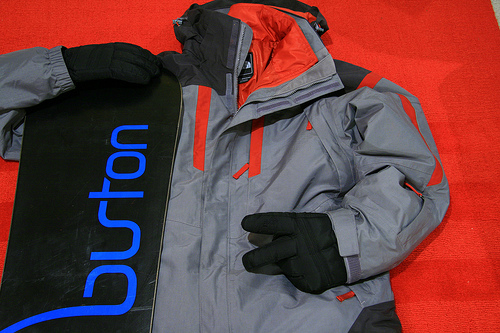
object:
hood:
[172, 0, 338, 70]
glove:
[63, 39, 162, 85]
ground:
[317, 127, 373, 182]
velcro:
[224, 19, 254, 108]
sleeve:
[322, 58, 451, 283]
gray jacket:
[1, 1, 450, 331]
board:
[0, 67, 184, 333]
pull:
[232, 163, 248, 180]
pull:
[336, 290, 355, 303]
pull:
[305, 121, 312, 130]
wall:
[308, 108, 362, 158]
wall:
[192, 39, 259, 111]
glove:
[236, 206, 346, 294]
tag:
[238, 49, 254, 84]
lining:
[229, 7, 316, 108]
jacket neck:
[162, 2, 348, 105]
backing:
[319, 5, 493, 333]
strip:
[364, 91, 444, 185]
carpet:
[0, 0, 499, 333]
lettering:
[0, 124, 150, 331]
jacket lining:
[227, 1, 317, 106]